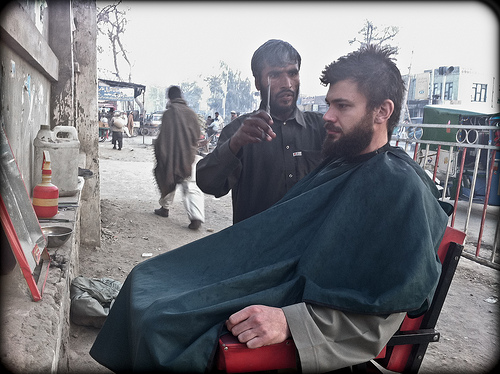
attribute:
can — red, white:
[30, 147, 60, 217]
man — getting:
[89, 42, 454, 372]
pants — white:
[159, 148, 204, 219]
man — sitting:
[309, 45, 415, 177]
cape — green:
[115, 163, 420, 371]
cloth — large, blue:
[173, 190, 498, 321]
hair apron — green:
[101, 150, 458, 371]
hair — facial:
[323, 82, 391, 159]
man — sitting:
[83, 47, 476, 364]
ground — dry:
[68, 134, 495, 370]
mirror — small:
[0, 123, 40, 272]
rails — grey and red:
[430, 128, 499, 274]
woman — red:
[15, 72, 47, 123]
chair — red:
[380, 260, 438, 369]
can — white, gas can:
[26, 111, 114, 260]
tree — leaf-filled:
[350, 18, 399, 63]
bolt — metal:
[427, 321, 440, 353]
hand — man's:
[225, 303, 285, 347]